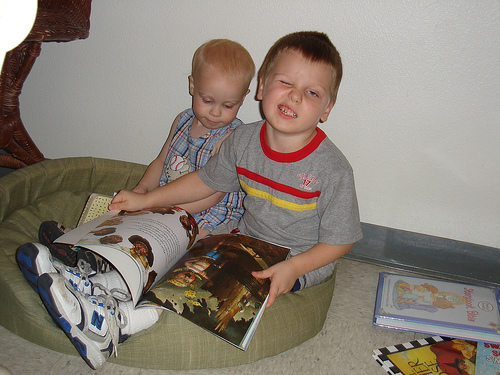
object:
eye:
[295, 90, 323, 101]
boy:
[10, 30, 366, 339]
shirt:
[197, 119, 362, 293]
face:
[265, 42, 327, 128]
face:
[192, 64, 238, 127]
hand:
[248, 258, 300, 309]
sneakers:
[28, 268, 128, 373]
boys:
[37, 37, 254, 272]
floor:
[0, 256, 489, 373]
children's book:
[371, 259, 498, 350]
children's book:
[372, 330, 485, 373]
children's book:
[472, 339, 499, 374]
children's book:
[51, 195, 295, 357]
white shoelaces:
[92, 288, 126, 356]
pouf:
[33, 166, 90, 208]